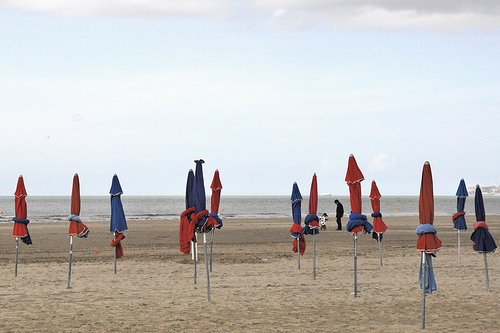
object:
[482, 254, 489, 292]
pole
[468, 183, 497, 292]
umbrella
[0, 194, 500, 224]
surf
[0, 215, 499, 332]
sand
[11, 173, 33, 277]
umbrella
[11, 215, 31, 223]
strap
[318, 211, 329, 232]
child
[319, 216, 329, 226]
coat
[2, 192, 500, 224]
sea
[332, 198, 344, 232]
man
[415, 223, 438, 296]
tie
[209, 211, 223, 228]
tie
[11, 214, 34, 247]
tie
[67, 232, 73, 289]
silver pole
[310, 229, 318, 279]
silver pole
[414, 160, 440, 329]
folded umbrellas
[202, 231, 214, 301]
pole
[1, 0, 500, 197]
clouds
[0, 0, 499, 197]
sky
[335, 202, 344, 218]
clothes